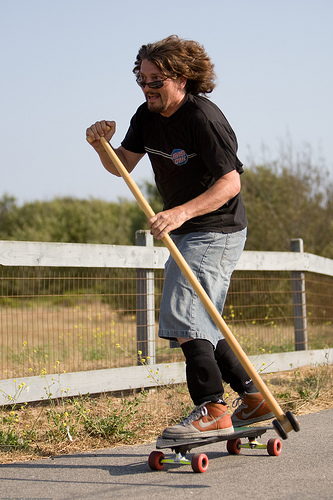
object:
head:
[132, 34, 218, 112]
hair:
[133, 34, 219, 97]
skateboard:
[149, 423, 281, 472]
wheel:
[268, 438, 282, 456]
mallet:
[100, 137, 298, 438]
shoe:
[163, 403, 233, 439]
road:
[0, 413, 330, 499]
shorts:
[158, 224, 249, 345]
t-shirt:
[121, 93, 248, 233]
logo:
[144, 145, 197, 166]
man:
[88, 37, 277, 439]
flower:
[137, 348, 145, 358]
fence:
[0, 239, 333, 405]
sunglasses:
[138, 74, 172, 88]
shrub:
[2, 199, 144, 294]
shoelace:
[180, 405, 207, 425]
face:
[137, 59, 175, 113]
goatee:
[144, 89, 166, 113]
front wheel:
[189, 450, 208, 472]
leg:
[161, 227, 247, 399]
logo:
[197, 412, 226, 428]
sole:
[166, 427, 235, 437]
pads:
[182, 338, 223, 413]